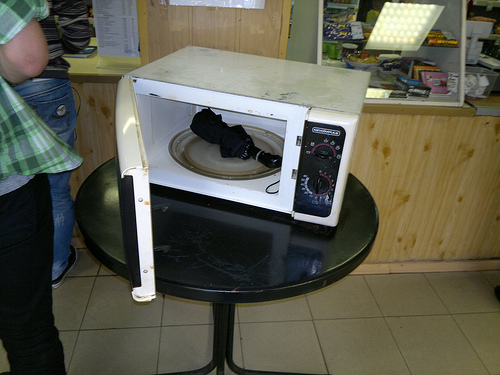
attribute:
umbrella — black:
[183, 112, 284, 172]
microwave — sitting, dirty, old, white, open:
[116, 31, 363, 250]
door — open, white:
[108, 75, 164, 299]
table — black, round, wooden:
[82, 175, 327, 375]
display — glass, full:
[321, 10, 485, 103]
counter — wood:
[360, 110, 500, 130]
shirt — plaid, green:
[3, 7, 69, 193]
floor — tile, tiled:
[74, 254, 496, 367]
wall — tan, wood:
[77, 87, 495, 262]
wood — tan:
[70, 78, 488, 258]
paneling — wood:
[73, 92, 494, 254]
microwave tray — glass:
[172, 132, 284, 176]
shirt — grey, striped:
[28, 2, 92, 70]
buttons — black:
[306, 146, 336, 198]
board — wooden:
[68, 64, 150, 76]